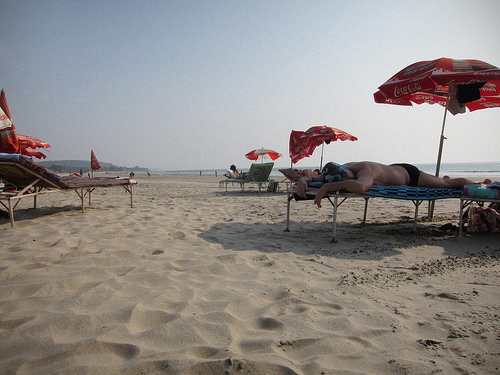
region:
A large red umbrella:
[342, 25, 497, 205]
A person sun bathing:
[268, 146, 489, 216]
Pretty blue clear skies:
[35, 16, 431, 147]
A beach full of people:
[5, 47, 496, 333]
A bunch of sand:
[8, 227, 489, 365]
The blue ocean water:
[396, 140, 496, 173]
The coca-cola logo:
[392, 63, 428, 104]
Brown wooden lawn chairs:
[5, 150, 151, 218]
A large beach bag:
[440, 196, 493, 237]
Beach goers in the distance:
[123, 166, 226, 186]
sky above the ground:
[121, 45, 189, 102]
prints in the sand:
[68, 235, 226, 366]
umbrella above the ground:
[385, 38, 473, 128]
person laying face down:
[308, 140, 440, 224]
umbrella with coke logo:
[368, 41, 478, 119]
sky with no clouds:
[121, 26, 219, 106]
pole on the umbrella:
[426, 120, 458, 157]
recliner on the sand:
[1, 169, 141, 231]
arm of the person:
[296, 173, 379, 225]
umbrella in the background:
[242, 127, 287, 175]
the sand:
[71, 192, 278, 339]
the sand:
[121, 223, 240, 360]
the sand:
[156, 268, 212, 358]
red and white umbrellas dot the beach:
[2, 55, 499, 162]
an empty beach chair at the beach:
[1, 153, 141, 227]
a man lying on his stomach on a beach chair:
[286, 162, 490, 238]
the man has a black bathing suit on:
[389, 160, 425, 188]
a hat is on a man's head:
[317, 160, 352, 187]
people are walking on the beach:
[126, 163, 224, 184]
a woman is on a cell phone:
[216, 160, 250, 194]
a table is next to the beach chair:
[456, 180, 498, 244]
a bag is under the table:
[463, 204, 499, 240]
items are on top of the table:
[460, 177, 499, 204]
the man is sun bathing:
[292, 151, 474, 208]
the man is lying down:
[276, 154, 475, 212]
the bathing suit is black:
[399, 150, 422, 185]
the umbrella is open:
[382, 40, 498, 123]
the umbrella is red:
[382, 34, 492, 126]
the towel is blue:
[372, 184, 448, 201]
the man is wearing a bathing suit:
[395, 155, 420, 194]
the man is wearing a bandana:
[305, 160, 347, 187]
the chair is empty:
[10, 147, 144, 227]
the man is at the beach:
[269, 145, 473, 231]